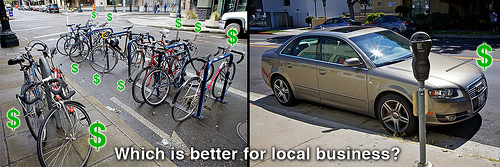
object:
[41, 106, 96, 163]
spokes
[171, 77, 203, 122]
wheel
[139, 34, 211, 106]
bicycles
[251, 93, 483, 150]
shadow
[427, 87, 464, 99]
headlight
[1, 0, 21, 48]
light pole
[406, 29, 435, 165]
parking meter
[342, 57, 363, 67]
rear mirror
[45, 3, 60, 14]
car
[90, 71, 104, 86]
signs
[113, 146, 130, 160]
words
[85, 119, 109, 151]
dollar sign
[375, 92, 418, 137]
wheel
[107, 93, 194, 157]
arrow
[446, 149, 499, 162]
grass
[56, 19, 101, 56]
bicycles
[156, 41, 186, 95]
bicycle rack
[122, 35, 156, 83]
bicycle rack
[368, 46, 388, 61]
sun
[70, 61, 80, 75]
dollar signs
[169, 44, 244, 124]
bicycle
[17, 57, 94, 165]
bicycle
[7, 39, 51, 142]
bicycle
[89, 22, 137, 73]
bicycle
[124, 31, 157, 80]
bicycle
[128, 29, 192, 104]
bikes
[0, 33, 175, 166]
sidewalk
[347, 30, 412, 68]
windshield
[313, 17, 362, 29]
car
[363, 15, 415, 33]
car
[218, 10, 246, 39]
car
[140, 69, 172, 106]
tires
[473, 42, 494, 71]
dollar sign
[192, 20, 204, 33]
sign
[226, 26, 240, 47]
dollar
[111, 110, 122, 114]
trash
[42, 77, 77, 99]
handlebars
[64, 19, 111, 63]
bicycle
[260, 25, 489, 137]
gold car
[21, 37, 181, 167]
curb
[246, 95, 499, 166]
curb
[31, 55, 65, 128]
racks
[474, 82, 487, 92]
company emblem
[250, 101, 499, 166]
sidewalk's crack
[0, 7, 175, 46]
street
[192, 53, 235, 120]
guard rail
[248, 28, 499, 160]
street